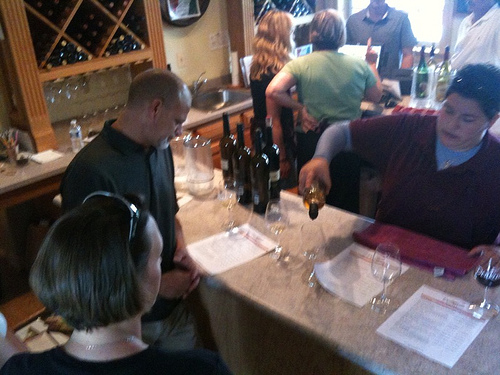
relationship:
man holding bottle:
[303, 63, 498, 257] [303, 173, 328, 220]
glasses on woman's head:
[77, 182, 154, 240] [30, 186, 163, 333]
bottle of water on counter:
[37, 96, 132, 180] [0, 105, 214, 195]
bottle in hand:
[258, 151, 396, 252] [297, 152, 332, 195]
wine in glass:
[298, 240, 322, 256] [296, 216, 327, 287]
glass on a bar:
[367, 241, 408, 315] [189, 198, 484, 371]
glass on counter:
[349, 222, 421, 332] [189, 196, 480, 355]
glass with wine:
[468, 244, 499, 324] [470, 267, 499, 292]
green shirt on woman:
[294, 59, 366, 126] [266, 3, 390, 215]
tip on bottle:
[307, 200, 333, 230] [300, 163, 353, 255]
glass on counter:
[367, 241, 408, 315] [161, 151, 498, 371]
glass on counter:
[468, 249, 500, 323] [161, 151, 498, 371]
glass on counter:
[291, 216, 324, 293] [161, 151, 498, 371]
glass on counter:
[259, 196, 289, 263] [161, 151, 498, 371]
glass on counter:
[215, 172, 245, 244] [161, 151, 498, 371]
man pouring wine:
[297, 63, 500, 277] [301, 177, 326, 218]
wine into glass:
[301, 177, 326, 218] [298, 220, 330, 288]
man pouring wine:
[297, 63, 500, 277] [301, 187, 326, 207]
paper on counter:
[375, 296, 490, 370] [161, 151, 498, 371]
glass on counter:
[296, 216, 327, 287] [161, 151, 498, 371]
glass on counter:
[263, 196, 292, 263] [161, 151, 498, 371]